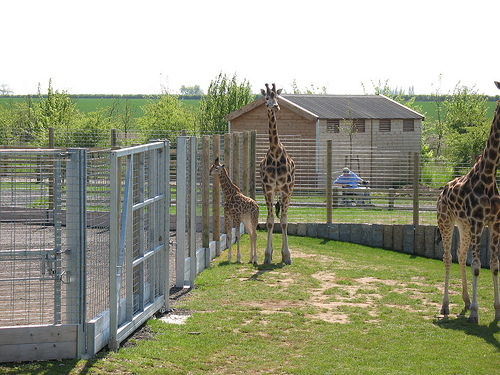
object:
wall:
[296, 212, 456, 264]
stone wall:
[341, 221, 426, 248]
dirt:
[323, 295, 383, 323]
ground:
[266, 264, 391, 345]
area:
[0, 128, 225, 327]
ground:
[385, 185, 407, 226]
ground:
[309, 275, 426, 325]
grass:
[288, 193, 436, 228]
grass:
[135, 305, 275, 375]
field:
[2, 95, 492, 367]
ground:
[2, 181, 495, 372]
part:
[279, 322, 300, 350]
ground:
[229, 282, 248, 307]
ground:
[289, 257, 396, 332]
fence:
[247, 132, 496, 269]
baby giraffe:
[206, 156, 259, 262]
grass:
[251, 249, 431, 353]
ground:
[3, 230, 498, 373]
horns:
[264, 82, 277, 93]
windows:
[325, 119, 340, 133]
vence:
[256, 129, 491, 230]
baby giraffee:
[208, 156, 257, 263]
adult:
[258, 81, 298, 267]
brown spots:
[464, 184, 489, 214]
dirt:
[0, 176, 488, 373]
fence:
[39, 113, 243, 322]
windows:
[351, 117, 366, 133]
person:
[330, 167, 370, 205]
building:
[226, 89, 424, 195]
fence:
[1, 136, 248, 360]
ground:
[263, 271, 408, 342]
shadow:
[432, 305, 499, 355]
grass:
[305, 288, 405, 345]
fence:
[322, 140, 459, 210]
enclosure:
[1, 130, 498, 372]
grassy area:
[0, 230, 498, 372]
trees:
[431, 85, 491, 170]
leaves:
[11, 82, 109, 129]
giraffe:
[434, 78, 498, 330]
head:
[257, 82, 280, 114]